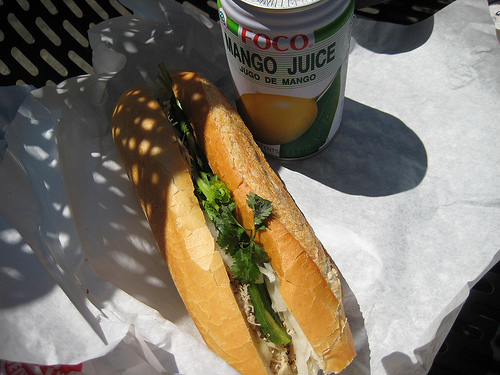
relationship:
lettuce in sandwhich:
[212, 206, 273, 280] [122, 68, 327, 354]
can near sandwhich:
[221, 6, 365, 162] [122, 68, 327, 354]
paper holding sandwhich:
[39, 176, 135, 340] [122, 68, 327, 354]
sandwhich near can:
[122, 68, 327, 354] [221, 6, 365, 162]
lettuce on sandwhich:
[212, 206, 273, 280] [122, 68, 327, 354]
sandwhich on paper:
[122, 68, 327, 354] [39, 176, 135, 340]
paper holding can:
[39, 176, 135, 340] [221, 6, 365, 162]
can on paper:
[221, 6, 365, 162] [39, 176, 135, 340]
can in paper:
[221, 6, 365, 162] [39, 176, 135, 340]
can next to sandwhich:
[221, 6, 365, 162] [122, 68, 327, 354]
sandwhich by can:
[122, 68, 327, 354] [221, 6, 365, 162]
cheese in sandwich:
[233, 275, 297, 370] [157, 102, 357, 371]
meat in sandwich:
[221, 255, 298, 373] [157, 102, 357, 371]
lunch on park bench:
[157, 105, 372, 362] [2, 1, 494, 371]